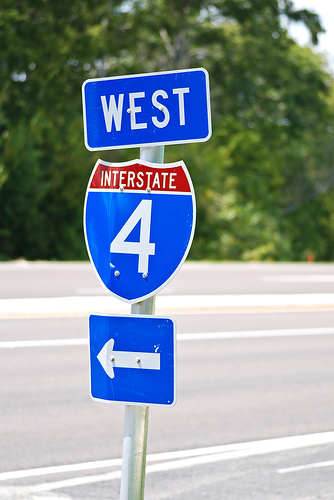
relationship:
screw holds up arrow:
[109, 356, 116, 363] [94, 337, 166, 384]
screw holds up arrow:
[134, 356, 142, 363] [94, 337, 166, 384]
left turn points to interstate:
[87, 314, 177, 408] [10, 284, 85, 468]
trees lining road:
[0, 0, 334, 269] [0, 261, 334, 500]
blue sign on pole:
[81, 66, 212, 152] [118, 400, 144, 500]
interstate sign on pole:
[81, 158, 197, 305] [118, 400, 144, 500]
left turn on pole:
[87, 314, 177, 408] [118, 400, 144, 500]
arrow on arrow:
[96, 337, 160, 379] [94, 337, 166, 384]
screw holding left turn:
[111, 357, 115, 362] [87, 314, 177, 408]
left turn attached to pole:
[87, 314, 177, 408] [124, 301, 147, 498]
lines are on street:
[0, 427, 333, 495] [3, 260, 331, 498]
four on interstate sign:
[107, 198, 155, 272] [81, 158, 197, 305]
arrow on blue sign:
[97, 335, 162, 376] [72, 65, 216, 146]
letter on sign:
[101, 84, 189, 132] [65, 66, 229, 156]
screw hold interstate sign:
[146, 186, 150, 192] [81, 158, 197, 305]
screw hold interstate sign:
[118, 185, 123, 192] [81, 158, 197, 305]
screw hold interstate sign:
[140, 272, 147, 277] [81, 158, 197, 305]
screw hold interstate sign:
[113, 270, 118, 277] [81, 158, 197, 305]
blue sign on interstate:
[81, 66, 212, 152] [6, 262, 318, 497]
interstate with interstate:
[212, 263, 305, 383] [0, 261, 334, 500]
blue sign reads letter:
[81, 66, 212, 152] [101, 84, 189, 132]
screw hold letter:
[157, 103, 164, 111] [101, 84, 189, 132]